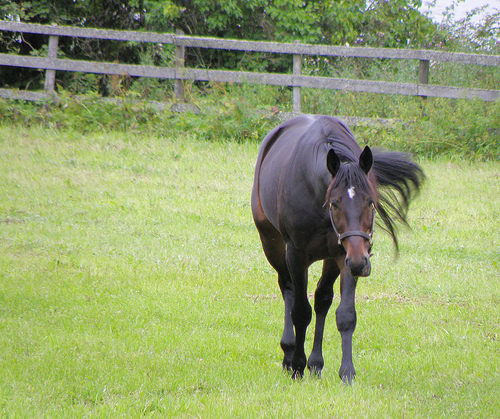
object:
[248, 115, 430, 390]
horse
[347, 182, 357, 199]
white dot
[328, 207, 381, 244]
harness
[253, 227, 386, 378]
4 legs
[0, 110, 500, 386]
grass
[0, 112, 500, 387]
field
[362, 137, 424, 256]
tail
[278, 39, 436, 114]
fence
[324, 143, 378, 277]
head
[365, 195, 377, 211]
eye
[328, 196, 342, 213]
eye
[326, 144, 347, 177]
ear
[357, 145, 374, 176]
ear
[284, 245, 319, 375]
leg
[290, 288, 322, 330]
knee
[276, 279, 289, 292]
knee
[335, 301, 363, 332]
knee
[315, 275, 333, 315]
knee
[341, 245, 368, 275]
nose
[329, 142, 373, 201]
mane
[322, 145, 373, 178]
ears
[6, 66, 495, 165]
bush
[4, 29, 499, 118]
rail